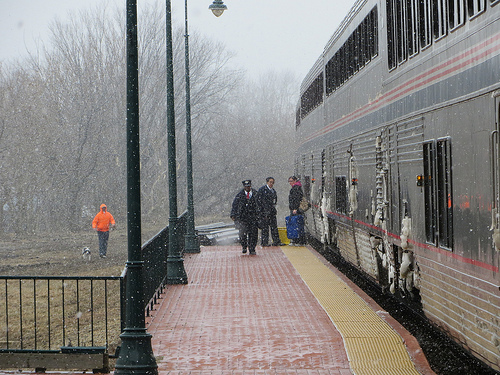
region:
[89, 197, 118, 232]
A bright orange hoodie.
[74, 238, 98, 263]
A dog.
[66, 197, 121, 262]
A man walking a dog.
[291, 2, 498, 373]
A train stopped.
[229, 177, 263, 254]
A man in a uniform.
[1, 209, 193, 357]
A small metal fence.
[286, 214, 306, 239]
A blue bag.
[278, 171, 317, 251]
A woman standing beside the end of a train.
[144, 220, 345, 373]
A bricked walkway.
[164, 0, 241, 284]
A street light.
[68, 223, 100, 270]
A Dog on a Leash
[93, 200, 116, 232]
A Man with a Bright Orange Coat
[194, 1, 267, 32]
An Unlit Street Lamp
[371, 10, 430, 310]
Snow Covered Parts of the Train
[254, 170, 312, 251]
Passengers Waiting To Board Train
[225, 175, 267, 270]
Train Conductor Walking Away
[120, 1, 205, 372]
Dark Green Lamp Posts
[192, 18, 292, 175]
Snowfall Reducing the Visibility of the Trees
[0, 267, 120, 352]
Metal, Dark Green Fence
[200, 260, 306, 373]
Snow Covered Red Brick Pavement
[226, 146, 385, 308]
Men by the train.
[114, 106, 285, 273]
Snow in the air.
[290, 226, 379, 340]
Yellow stripe on the ground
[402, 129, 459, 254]
Window on the train.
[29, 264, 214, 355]
Fence on the ground.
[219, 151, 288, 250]
Man wearing a tie.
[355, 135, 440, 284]
Door on the train.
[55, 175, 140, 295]
person in an orange hoodie.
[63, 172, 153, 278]
Person walking a dog.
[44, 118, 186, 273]
Tree in the background.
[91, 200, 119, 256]
Man walking black and white dog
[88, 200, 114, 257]
Man wearing orange sweater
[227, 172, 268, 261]
Man wearing Amtrak cap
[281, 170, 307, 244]
Woman holding blue suitcase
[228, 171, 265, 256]
Man wearing red tie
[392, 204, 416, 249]
Snow on train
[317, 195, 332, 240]
Snow on train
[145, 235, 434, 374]
Red ground is wet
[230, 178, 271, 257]
Man is walking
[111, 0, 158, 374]
Tall metal light post next to small black metal fence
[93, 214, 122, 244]
man has orange coat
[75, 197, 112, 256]
coat has orange hood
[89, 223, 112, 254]
man has blue pants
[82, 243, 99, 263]
man has white dog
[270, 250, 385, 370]
yellow stripe on platform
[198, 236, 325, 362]
platform is red brick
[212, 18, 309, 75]
sky is grey and wintery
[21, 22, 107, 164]
trees are tall and bare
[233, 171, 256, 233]
conductor has black hat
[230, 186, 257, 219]
conductor has dark coat